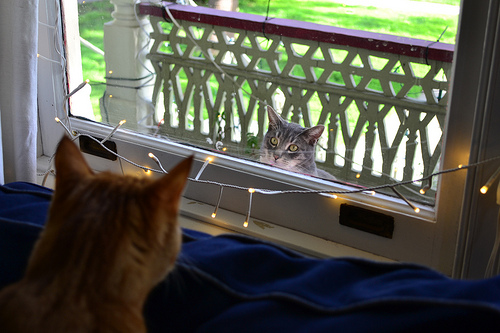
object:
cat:
[257, 105, 324, 177]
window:
[58, 0, 466, 209]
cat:
[3, 130, 195, 332]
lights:
[477, 176, 492, 198]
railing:
[102, 0, 461, 200]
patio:
[56, 1, 464, 215]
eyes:
[267, 137, 277, 147]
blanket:
[1, 180, 496, 332]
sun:
[310, 0, 467, 22]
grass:
[76, 0, 462, 137]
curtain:
[6, 0, 40, 183]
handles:
[336, 202, 396, 240]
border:
[139, 0, 458, 63]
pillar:
[96, 0, 152, 131]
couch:
[0, 179, 499, 333]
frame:
[38, 0, 477, 272]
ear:
[304, 122, 327, 143]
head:
[41, 131, 196, 276]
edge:
[30, 116, 451, 270]